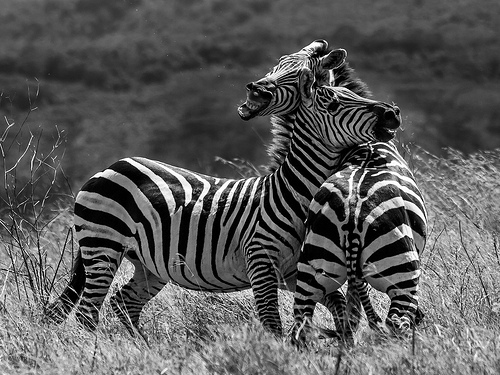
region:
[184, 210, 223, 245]
part of a stomach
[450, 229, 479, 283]
part of a grass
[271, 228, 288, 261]
part of a chesr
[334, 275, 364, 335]
part of a tail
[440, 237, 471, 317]
part of a grass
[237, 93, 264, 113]
the teeth of the zebra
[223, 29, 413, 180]
the zebras nuzzle their heads together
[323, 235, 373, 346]
the stripped tail of the zebra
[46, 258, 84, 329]
the furry black tail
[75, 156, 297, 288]
the stripes on the zebras back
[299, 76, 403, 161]
the head of the zebra on the others back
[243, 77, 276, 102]
the nostrils of the zebra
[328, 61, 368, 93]
the hair of the zebra behind the head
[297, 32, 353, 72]
the ears sticking up in the air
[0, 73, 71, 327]
the bare twig sticking up behind the zebra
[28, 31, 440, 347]
two zebras fighting in the wild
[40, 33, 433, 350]
two zebras fighting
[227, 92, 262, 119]
the mouth of a zebra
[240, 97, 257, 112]
the teeth of a zebra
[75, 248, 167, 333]
the rear legs of a zebra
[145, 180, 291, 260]
the stripes of a zebra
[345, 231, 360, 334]
the tail of a zebra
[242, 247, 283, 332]
the front leg of a zebra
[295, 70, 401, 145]
the head of a zebra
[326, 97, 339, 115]
the eye of a zebra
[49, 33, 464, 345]
two zebras in the wild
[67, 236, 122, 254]
stripe on the zebra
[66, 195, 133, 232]
stripe on the zebra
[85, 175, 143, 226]
stripe on the zebra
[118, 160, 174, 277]
stripe on the zebra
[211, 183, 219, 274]
stripe on the zebra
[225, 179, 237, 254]
stripe on the zebra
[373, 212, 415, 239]
stripe on the zebra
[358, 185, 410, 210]
stripe on the zebra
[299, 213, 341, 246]
stripe on the zebra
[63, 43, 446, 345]
zebras in the field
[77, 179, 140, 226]
stripe of the zebra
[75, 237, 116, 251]
stripe of the zebra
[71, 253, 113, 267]
stripe of the zebra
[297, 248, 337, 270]
stripe of the zebra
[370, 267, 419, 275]
stripe of the zebra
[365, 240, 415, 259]
stripe of the zebra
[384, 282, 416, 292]
stripe of the zebra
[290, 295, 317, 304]
stripe of the zebra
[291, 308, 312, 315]
stripe of the zebra